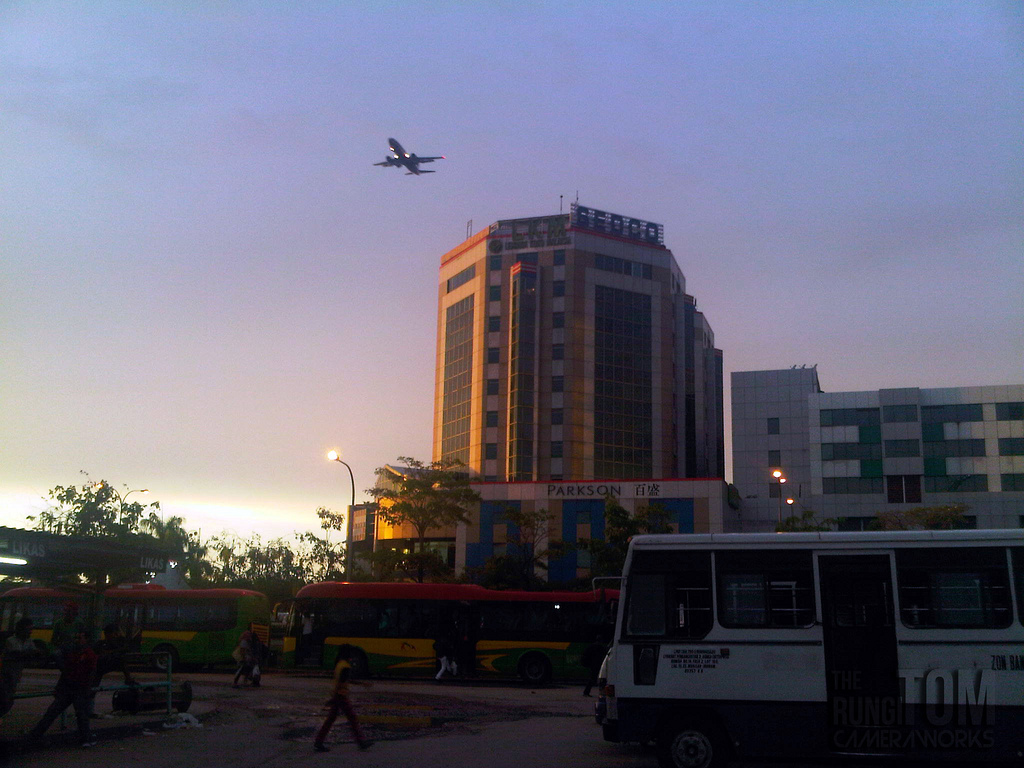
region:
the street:
[437, 724, 530, 764]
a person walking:
[314, 646, 381, 746]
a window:
[628, 571, 686, 645]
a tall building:
[448, 226, 687, 493]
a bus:
[594, 514, 1012, 743]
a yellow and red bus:
[338, 582, 440, 660]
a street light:
[314, 431, 349, 467]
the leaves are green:
[76, 484, 165, 549]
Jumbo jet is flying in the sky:
[372, 112, 456, 211]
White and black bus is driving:
[587, 511, 1003, 767]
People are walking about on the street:
[4, 599, 423, 765]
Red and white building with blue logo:
[386, 197, 753, 539]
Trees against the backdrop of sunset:
[0, 475, 371, 638]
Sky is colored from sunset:
[151, 52, 962, 430]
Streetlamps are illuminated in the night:
[304, 431, 410, 556]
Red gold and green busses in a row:
[3, 563, 637, 696]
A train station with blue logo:
[0, 508, 219, 630]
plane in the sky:
[349, 129, 474, 197]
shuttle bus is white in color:
[594, 521, 1018, 747]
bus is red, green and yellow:
[296, 585, 626, 690]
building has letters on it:
[548, 468, 626, 504]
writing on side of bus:
[666, 644, 728, 673]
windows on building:
[828, 411, 880, 491]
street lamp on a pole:
[321, 429, 367, 490]